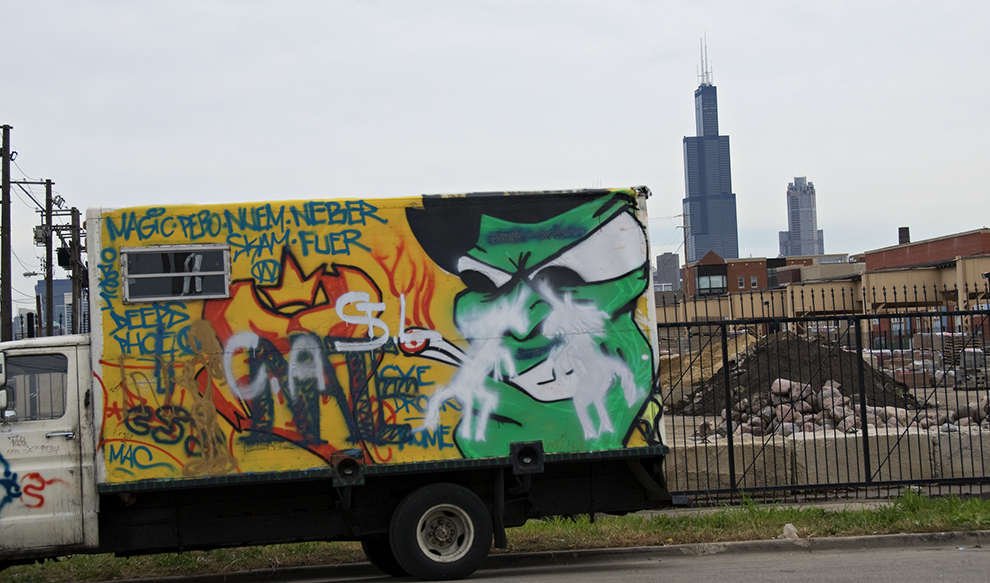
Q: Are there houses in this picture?
A: No, there are no houses.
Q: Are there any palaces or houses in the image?
A: No, there are no houses or palaces.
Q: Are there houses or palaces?
A: No, there are no houses or palaces.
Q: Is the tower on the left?
A: No, the tower is on the right of the image.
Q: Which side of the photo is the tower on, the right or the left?
A: The tower is on the right of the image.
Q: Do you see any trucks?
A: Yes, there is a truck.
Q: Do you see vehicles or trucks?
A: Yes, there is a truck.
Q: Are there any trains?
A: No, there are no trains.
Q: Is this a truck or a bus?
A: This is a truck.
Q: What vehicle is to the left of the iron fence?
A: The vehicle is a truck.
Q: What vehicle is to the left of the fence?
A: The vehicle is a truck.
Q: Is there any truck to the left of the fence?
A: Yes, there is a truck to the left of the fence.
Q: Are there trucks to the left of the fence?
A: Yes, there is a truck to the left of the fence.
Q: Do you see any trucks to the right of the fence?
A: No, the truck is to the left of the fence.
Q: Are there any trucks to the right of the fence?
A: No, the truck is to the left of the fence.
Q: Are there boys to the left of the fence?
A: No, there is a truck to the left of the fence.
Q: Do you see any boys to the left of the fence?
A: No, there is a truck to the left of the fence.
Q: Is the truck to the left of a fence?
A: Yes, the truck is to the left of a fence.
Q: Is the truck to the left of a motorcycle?
A: No, the truck is to the left of a fence.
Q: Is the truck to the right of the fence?
A: No, the truck is to the left of the fence.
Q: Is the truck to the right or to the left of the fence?
A: The truck is to the left of the fence.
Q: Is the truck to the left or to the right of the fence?
A: The truck is to the left of the fence.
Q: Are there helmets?
A: No, there are no helmets.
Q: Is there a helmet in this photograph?
A: No, there are no helmets.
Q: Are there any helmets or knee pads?
A: No, there are no helmets or knee pads.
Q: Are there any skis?
A: No, there are no skis.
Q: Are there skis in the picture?
A: No, there are no skis.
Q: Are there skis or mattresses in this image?
A: No, there are no skis or mattresses.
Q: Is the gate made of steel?
A: Yes, the gate is made of steel.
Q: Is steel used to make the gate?
A: Yes, the gate is made of steel.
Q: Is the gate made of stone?
A: No, the gate is made of steel.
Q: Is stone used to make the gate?
A: No, the gate is made of steel.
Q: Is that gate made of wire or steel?
A: The gate is made of steel.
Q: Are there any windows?
A: Yes, there is a window.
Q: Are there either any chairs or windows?
A: Yes, there is a window.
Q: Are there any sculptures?
A: No, there are no sculptures.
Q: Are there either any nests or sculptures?
A: No, there are no sculptures or nests.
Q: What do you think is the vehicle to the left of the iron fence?
A: The vehicle is a trailer.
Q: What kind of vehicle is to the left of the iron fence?
A: The vehicle is a trailer.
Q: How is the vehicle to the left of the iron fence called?
A: The vehicle is a trailer.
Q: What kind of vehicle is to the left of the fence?
A: The vehicle is a trailer.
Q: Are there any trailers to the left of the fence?
A: Yes, there is a trailer to the left of the fence.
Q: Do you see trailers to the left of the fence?
A: Yes, there is a trailer to the left of the fence.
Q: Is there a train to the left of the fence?
A: No, there is a trailer to the left of the fence.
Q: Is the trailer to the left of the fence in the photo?
A: Yes, the trailer is to the left of the fence.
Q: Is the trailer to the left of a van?
A: No, the trailer is to the left of the fence.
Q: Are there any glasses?
A: No, there are no glasses.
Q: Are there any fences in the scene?
A: Yes, there is a fence.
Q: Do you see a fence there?
A: Yes, there is a fence.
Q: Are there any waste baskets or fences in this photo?
A: Yes, there is a fence.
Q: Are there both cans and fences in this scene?
A: No, there is a fence but no cans.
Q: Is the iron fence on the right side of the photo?
A: Yes, the fence is on the right of the image.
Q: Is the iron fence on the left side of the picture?
A: No, the fence is on the right of the image.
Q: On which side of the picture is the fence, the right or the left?
A: The fence is on the right of the image.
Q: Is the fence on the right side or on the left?
A: The fence is on the right of the image.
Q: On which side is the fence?
A: The fence is on the right of the image.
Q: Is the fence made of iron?
A: Yes, the fence is made of iron.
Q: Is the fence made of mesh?
A: No, the fence is made of iron.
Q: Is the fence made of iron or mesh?
A: The fence is made of iron.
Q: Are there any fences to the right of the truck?
A: Yes, there is a fence to the right of the truck.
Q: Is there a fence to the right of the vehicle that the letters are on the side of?
A: Yes, there is a fence to the right of the truck.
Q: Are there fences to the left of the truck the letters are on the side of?
A: No, the fence is to the right of the truck.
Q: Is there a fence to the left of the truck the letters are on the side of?
A: No, the fence is to the right of the truck.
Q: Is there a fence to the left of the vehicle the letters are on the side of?
A: No, the fence is to the right of the truck.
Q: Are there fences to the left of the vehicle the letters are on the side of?
A: No, the fence is to the right of the truck.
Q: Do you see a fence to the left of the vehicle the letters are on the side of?
A: No, the fence is to the right of the truck.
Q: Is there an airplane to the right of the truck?
A: No, there is a fence to the right of the truck.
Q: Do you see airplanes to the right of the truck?
A: No, there is a fence to the right of the truck.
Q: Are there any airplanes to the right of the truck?
A: No, there is a fence to the right of the truck.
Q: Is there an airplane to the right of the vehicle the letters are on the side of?
A: No, there is a fence to the right of the truck.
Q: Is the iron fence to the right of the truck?
A: Yes, the fence is to the right of the truck.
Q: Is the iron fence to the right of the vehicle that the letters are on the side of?
A: Yes, the fence is to the right of the truck.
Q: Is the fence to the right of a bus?
A: No, the fence is to the right of the truck.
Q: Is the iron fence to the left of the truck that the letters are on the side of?
A: No, the fence is to the right of the truck.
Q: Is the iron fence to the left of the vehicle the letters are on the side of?
A: No, the fence is to the right of the truck.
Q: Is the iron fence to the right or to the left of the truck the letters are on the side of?
A: The fence is to the right of the truck.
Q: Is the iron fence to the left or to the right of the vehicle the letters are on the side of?
A: The fence is to the right of the truck.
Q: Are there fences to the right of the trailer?
A: Yes, there is a fence to the right of the trailer.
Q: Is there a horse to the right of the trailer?
A: No, there is a fence to the right of the trailer.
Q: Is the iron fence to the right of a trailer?
A: Yes, the fence is to the right of a trailer.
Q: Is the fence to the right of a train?
A: No, the fence is to the right of a trailer.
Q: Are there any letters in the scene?
A: Yes, there are letters.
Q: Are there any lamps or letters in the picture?
A: Yes, there are letters.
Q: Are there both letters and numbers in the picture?
A: No, there are letters but no numbers.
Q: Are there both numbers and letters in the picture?
A: No, there are letters but no numbers.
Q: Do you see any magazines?
A: No, there are no magazines.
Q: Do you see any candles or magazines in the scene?
A: No, there are no magazines or candles.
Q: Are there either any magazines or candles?
A: No, there are no magazines or candles.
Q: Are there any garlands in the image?
A: No, there are no garlands.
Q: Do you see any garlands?
A: No, there are no garlands.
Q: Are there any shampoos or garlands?
A: No, there are no garlands or shampoos.